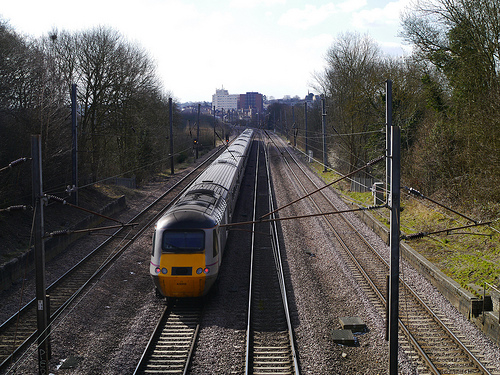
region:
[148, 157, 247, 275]
this is a train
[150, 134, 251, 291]
the train is long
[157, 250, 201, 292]
the front is yellow in color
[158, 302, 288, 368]
these are the rails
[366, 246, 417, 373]
this is a pole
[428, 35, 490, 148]
trees are beside the railway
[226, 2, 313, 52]
this is the sky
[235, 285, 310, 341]
the rails are metallic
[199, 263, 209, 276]
the light is on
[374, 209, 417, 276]
the pole is straight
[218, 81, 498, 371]
metal pole with horizontal arms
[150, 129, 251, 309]
silver passenger train with yellow and silver engine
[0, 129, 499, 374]
four sets of train tracks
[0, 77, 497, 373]
metal poles with overhead train wires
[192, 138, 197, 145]
train traffic signal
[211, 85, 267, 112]
multi-story city buildings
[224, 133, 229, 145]
train traffic signal beside tracks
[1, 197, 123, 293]
cement retaining wall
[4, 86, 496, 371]
train travelling on tracks outside of city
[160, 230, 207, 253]
Windshield of a moving train.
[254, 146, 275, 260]
Long tracks down the middle.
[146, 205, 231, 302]
Front car of the train.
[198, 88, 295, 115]
White and brown buildings.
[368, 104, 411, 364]
Brown telephone pole with lines running.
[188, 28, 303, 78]
Overcast and grey sky.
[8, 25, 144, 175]
Bare trees sticking out.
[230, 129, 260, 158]
Rear segment of the train.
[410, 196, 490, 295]
Mossy green grass on the side.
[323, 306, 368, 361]
Two wooden planks on the ground.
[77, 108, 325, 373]
The train is on the track.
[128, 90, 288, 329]
The train long.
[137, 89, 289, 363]
The train is gray and orange.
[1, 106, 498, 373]
The tracks have gravel between them.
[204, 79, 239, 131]
The building is white.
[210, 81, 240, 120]
The building is tall.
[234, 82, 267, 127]
The building is tall.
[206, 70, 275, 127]
Two buildings side by side.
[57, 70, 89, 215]
The pole is straight.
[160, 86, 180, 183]
The pole is straight.